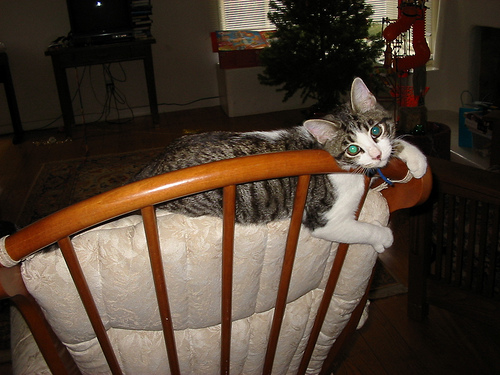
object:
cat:
[134, 74, 425, 250]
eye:
[344, 142, 362, 156]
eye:
[371, 123, 382, 136]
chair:
[0, 141, 428, 374]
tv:
[67, 1, 153, 39]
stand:
[44, 35, 160, 121]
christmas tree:
[259, 1, 390, 109]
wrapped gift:
[211, 28, 272, 52]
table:
[213, 49, 325, 116]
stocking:
[382, 1, 415, 42]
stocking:
[383, 0, 438, 72]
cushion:
[0, 186, 388, 374]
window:
[219, 0, 441, 65]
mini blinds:
[220, 1, 403, 57]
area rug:
[0, 110, 499, 332]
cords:
[44, 60, 217, 127]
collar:
[370, 164, 396, 186]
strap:
[1, 233, 23, 266]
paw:
[398, 147, 429, 180]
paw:
[369, 220, 391, 253]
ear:
[302, 118, 339, 143]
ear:
[351, 77, 375, 111]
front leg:
[305, 206, 392, 252]